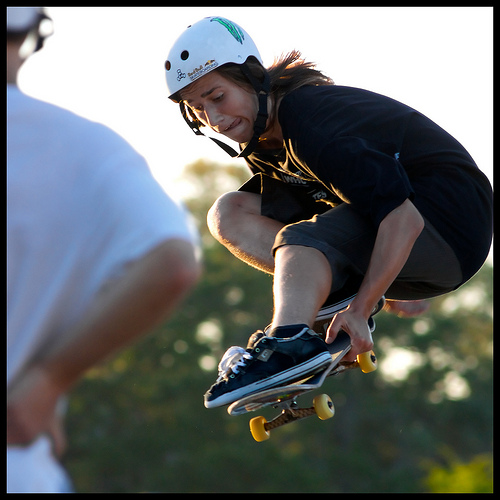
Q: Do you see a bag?
A: No, there are no bags.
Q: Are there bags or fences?
A: No, there are no bags or fences.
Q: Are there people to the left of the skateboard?
A: Yes, there is a person to the left of the skateboard.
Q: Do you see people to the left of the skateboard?
A: Yes, there is a person to the left of the skateboard.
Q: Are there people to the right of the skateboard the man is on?
A: No, the person is to the left of the skateboard.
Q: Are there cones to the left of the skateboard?
A: No, there is a person to the left of the skateboard.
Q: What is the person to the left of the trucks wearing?
A: The person is wearing a shirt.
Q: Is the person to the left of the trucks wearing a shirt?
A: Yes, the person is wearing a shirt.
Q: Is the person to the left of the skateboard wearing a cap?
A: No, the person is wearing a shirt.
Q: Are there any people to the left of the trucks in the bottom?
A: Yes, there is a person to the left of the trucks.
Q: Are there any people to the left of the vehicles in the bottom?
A: Yes, there is a person to the left of the trucks.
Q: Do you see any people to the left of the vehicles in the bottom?
A: Yes, there is a person to the left of the trucks.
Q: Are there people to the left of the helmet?
A: Yes, there is a person to the left of the helmet.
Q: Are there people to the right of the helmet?
A: No, the person is to the left of the helmet.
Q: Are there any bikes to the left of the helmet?
A: No, there is a person to the left of the helmet.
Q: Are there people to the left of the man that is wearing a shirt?
A: Yes, there is a person to the left of the man.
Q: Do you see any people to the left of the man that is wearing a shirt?
A: Yes, there is a person to the left of the man.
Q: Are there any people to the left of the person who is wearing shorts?
A: Yes, there is a person to the left of the man.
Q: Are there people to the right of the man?
A: No, the person is to the left of the man.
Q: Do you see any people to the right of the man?
A: No, the person is to the left of the man.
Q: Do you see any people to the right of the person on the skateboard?
A: No, the person is to the left of the man.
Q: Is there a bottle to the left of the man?
A: No, there is a person to the left of the man.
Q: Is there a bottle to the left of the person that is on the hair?
A: No, there is a person to the left of the man.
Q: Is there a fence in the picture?
A: No, there are no fences.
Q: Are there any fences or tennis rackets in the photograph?
A: No, there are no fences or tennis rackets.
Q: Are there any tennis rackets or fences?
A: No, there are no fences or tennis rackets.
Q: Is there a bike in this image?
A: No, there are no bikes.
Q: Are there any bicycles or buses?
A: No, there are no bicycles or buses.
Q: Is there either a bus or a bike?
A: No, there are no bikes or buses.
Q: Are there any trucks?
A: Yes, there are trucks.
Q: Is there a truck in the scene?
A: Yes, there are trucks.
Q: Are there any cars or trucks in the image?
A: Yes, there are trucks.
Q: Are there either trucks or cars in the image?
A: Yes, there are trucks.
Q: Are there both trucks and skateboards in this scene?
A: Yes, there are both trucks and a skateboard.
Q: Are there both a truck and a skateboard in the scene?
A: Yes, there are both a truck and a skateboard.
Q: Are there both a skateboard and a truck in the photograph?
A: Yes, there are both a truck and a skateboard.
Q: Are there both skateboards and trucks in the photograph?
A: Yes, there are both trucks and a skateboard.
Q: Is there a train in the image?
A: No, there are no trains.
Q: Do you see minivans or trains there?
A: No, there are no trains or minivans.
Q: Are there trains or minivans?
A: No, there are no trains or minivans.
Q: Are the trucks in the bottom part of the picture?
A: Yes, the trucks are in the bottom of the image.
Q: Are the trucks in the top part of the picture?
A: No, the trucks are in the bottom of the image.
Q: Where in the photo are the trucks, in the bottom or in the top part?
A: The trucks are in the bottom of the image.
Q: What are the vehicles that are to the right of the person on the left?
A: The vehicles are trucks.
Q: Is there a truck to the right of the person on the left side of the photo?
A: Yes, there are trucks to the right of the person.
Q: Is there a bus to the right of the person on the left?
A: No, there are trucks to the right of the person.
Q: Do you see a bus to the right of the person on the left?
A: No, there are trucks to the right of the person.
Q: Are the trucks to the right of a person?
A: Yes, the trucks are to the right of a person.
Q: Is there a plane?
A: No, there are no airplanes.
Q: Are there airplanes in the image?
A: No, there are no airplanes.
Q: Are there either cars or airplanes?
A: No, there are no airplanes or cars.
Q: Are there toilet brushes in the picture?
A: No, there are no toilet brushes.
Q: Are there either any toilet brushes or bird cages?
A: No, there are no toilet brushes or bird cages.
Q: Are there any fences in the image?
A: No, there are no fences.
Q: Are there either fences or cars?
A: No, there are no fences or cars.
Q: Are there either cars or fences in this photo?
A: No, there are no fences or cars.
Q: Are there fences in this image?
A: No, there are no fences.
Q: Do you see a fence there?
A: No, there are no fences.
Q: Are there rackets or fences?
A: No, there are no fences or rackets.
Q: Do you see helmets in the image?
A: Yes, there is a helmet.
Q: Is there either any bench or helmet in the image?
A: Yes, there is a helmet.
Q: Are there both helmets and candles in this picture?
A: No, there is a helmet but no candles.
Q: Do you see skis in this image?
A: No, there are no skis.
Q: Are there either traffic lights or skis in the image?
A: No, there are no skis or traffic lights.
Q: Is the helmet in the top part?
A: Yes, the helmet is in the top of the image.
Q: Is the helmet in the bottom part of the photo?
A: No, the helmet is in the top of the image.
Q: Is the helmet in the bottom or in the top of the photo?
A: The helmet is in the top of the image.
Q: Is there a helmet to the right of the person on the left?
A: Yes, there is a helmet to the right of the person.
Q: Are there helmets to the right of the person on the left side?
A: Yes, there is a helmet to the right of the person.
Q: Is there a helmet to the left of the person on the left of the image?
A: No, the helmet is to the right of the person.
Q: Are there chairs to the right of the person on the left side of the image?
A: No, there is a helmet to the right of the person.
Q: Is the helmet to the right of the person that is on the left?
A: Yes, the helmet is to the right of the person.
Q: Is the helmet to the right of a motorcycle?
A: No, the helmet is to the right of the person.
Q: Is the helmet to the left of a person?
A: No, the helmet is to the right of a person.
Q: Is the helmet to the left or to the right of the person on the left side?
A: The helmet is to the right of the person.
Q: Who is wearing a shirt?
A: The man is wearing a shirt.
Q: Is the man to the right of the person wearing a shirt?
A: Yes, the man is wearing a shirt.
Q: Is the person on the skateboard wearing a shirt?
A: Yes, the man is wearing a shirt.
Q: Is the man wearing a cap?
A: No, the man is wearing a shirt.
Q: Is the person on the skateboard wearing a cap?
A: No, the man is wearing a shirt.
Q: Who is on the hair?
A: The man is on the hair.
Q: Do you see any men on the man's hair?
A: Yes, there is a man on the hair.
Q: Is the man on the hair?
A: Yes, the man is on the hair.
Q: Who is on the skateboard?
A: The man is on the skateboard.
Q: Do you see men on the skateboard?
A: Yes, there is a man on the skateboard.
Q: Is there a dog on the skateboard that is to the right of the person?
A: No, there is a man on the skateboard.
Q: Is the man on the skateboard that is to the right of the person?
A: Yes, the man is on the skateboard.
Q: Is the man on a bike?
A: No, the man is on the skateboard.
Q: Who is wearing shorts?
A: The man is wearing shorts.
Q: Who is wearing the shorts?
A: The man is wearing shorts.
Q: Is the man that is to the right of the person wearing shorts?
A: Yes, the man is wearing shorts.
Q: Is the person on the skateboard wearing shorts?
A: Yes, the man is wearing shorts.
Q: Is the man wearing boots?
A: No, the man is wearing shorts.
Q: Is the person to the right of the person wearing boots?
A: No, the man is wearing shorts.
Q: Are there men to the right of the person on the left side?
A: Yes, there is a man to the right of the person.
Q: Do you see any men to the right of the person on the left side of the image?
A: Yes, there is a man to the right of the person.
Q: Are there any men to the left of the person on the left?
A: No, the man is to the right of the person.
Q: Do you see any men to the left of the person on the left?
A: No, the man is to the right of the person.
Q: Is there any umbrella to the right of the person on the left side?
A: No, there is a man to the right of the person.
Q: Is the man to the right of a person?
A: Yes, the man is to the right of a person.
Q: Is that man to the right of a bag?
A: No, the man is to the right of a person.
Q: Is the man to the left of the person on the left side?
A: No, the man is to the right of the person.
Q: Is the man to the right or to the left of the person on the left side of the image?
A: The man is to the right of the person.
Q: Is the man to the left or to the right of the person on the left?
A: The man is to the right of the person.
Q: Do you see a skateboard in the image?
A: Yes, there is a skateboard.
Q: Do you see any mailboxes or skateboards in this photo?
A: Yes, there is a skateboard.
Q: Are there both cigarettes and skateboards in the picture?
A: No, there is a skateboard but no cigarettes.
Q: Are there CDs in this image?
A: No, there are no cds.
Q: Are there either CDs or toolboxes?
A: No, there are no CDs or toolboxes.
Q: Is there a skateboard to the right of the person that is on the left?
A: Yes, there is a skateboard to the right of the person.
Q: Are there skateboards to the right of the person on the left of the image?
A: Yes, there is a skateboard to the right of the person.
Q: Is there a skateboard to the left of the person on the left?
A: No, the skateboard is to the right of the person.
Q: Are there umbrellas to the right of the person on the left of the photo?
A: No, there is a skateboard to the right of the person.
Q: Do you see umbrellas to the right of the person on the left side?
A: No, there is a skateboard to the right of the person.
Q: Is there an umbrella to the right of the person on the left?
A: No, there is a skateboard to the right of the person.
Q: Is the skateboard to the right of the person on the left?
A: Yes, the skateboard is to the right of the person.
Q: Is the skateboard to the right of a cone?
A: No, the skateboard is to the right of the person.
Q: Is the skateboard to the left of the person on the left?
A: No, the skateboard is to the right of the person.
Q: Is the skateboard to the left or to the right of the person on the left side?
A: The skateboard is to the right of the person.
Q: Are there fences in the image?
A: No, there are no fences.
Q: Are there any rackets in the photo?
A: No, there are no rackets.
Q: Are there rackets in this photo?
A: No, there are no rackets.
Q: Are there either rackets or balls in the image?
A: No, there are no rackets or balls.